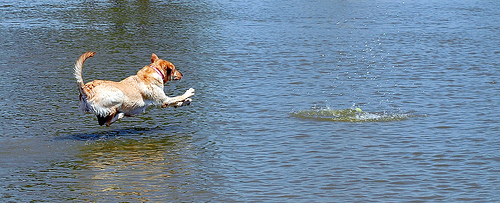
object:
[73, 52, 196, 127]
dog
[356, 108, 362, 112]
ball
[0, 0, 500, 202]
water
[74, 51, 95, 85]
tail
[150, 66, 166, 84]
collar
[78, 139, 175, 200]
reflection of dog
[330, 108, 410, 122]
splash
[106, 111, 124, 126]
leg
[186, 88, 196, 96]
paw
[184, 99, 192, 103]
paw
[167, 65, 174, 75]
ear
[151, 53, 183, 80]
head